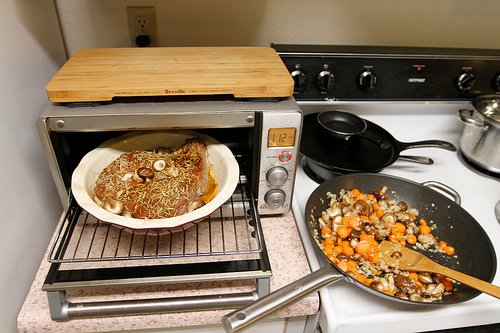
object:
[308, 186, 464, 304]
food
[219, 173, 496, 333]
pan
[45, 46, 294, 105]
cutting board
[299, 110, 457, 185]
pan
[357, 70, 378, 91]
knob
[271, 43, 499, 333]
stove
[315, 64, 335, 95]
knob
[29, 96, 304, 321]
microwave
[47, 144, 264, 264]
rack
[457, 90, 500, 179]
pot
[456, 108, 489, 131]
handle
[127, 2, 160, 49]
outlet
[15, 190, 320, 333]
countertop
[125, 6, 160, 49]
socket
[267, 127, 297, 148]
display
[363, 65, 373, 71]
writing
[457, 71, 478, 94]
knob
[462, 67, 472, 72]
writing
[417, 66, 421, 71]
light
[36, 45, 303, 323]
oven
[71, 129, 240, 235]
bowl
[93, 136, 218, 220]
food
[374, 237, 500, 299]
spoon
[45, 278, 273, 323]
handle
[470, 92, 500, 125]
lid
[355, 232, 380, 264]
carrots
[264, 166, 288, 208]
knobs